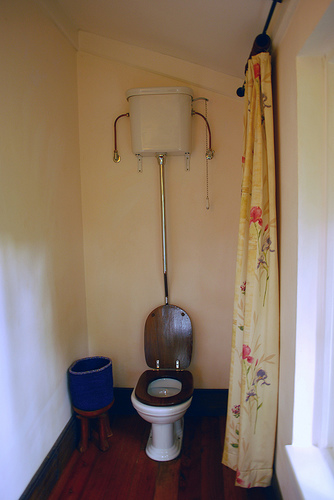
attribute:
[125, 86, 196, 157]
tank — white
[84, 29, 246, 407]
wall — white, peach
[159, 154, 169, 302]
pipe — metal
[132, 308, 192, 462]
toilet — porcelain, white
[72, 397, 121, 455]
stool — wooden, small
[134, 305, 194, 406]
seat — wooden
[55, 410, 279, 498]
floor — hardwood, wood, wooden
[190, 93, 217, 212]
chain — flusher, hanging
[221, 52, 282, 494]
curtain — yellow, flowered, hanging, floral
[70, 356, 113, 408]
basket — blue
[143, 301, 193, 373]
lid — wooden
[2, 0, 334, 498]
bathroom — small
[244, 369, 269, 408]
flower — blue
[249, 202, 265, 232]
flower — pink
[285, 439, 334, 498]
window sill — white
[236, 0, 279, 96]
curtain rod — black